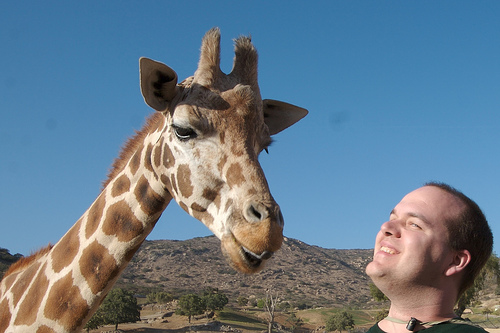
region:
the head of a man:
[361, 177, 494, 314]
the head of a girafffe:
[139, 20, 316, 280]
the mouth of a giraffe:
[227, 226, 288, 276]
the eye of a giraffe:
[165, 115, 202, 148]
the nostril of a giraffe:
[243, 200, 270, 227]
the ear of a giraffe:
[125, 42, 180, 110]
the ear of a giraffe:
[261, 97, 310, 147]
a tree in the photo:
[175, 287, 203, 329]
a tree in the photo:
[204, 288, 236, 328]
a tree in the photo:
[89, 293, 161, 332]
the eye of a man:
[401, 210, 425, 236]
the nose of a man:
[376, 215, 408, 237]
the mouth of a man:
[373, 238, 407, 262]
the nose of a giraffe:
[236, 191, 288, 229]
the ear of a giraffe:
[136, 48, 181, 120]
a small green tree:
[173, 287, 209, 330]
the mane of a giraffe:
[98, 96, 171, 193]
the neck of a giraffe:
[16, 114, 169, 331]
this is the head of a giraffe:
[138, 33, 304, 274]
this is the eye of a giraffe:
[171, 116, 201, 143]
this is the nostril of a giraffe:
[242, 196, 269, 225]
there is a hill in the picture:
[127, 214, 498, 309]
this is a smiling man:
[346, 174, 493, 331]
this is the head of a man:
[360, 178, 498, 309]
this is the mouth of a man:
[370, 242, 402, 256]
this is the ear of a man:
[451, 250, 476, 284]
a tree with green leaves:
[169, 289, 228, 330]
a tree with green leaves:
[105, 283, 145, 332]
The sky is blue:
[15, 11, 112, 128]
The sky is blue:
[301, 27, 448, 190]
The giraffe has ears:
[88, 33, 338, 145]